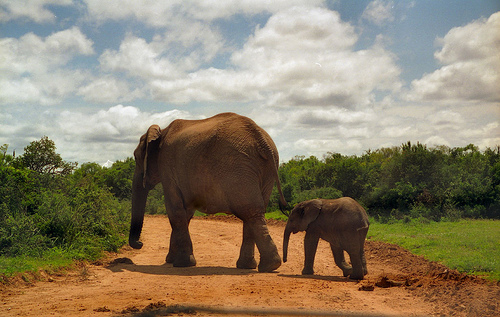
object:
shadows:
[102, 254, 256, 279]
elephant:
[127, 111, 292, 273]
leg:
[162, 188, 195, 268]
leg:
[236, 218, 261, 269]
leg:
[241, 212, 280, 274]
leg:
[300, 229, 318, 275]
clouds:
[2, 0, 497, 172]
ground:
[0, 176, 499, 317]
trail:
[0, 217, 498, 314]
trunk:
[128, 185, 148, 250]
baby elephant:
[276, 196, 374, 281]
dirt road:
[0, 211, 495, 315]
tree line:
[256, 137, 497, 213]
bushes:
[459, 148, 500, 216]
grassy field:
[376, 219, 498, 285]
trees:
[284, 154, 323, 201]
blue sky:
[0, 2, 500, 112]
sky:
[1, 0, 496, 145]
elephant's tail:
[268, 150, 292, 210]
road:
[1, 215, 498, 317]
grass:
[424, 233, 500, 282]